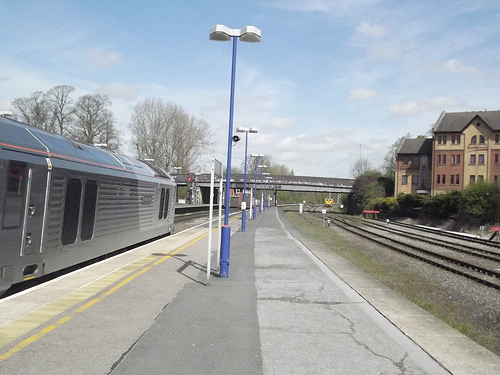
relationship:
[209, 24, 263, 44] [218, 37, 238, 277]
street light mounted on pole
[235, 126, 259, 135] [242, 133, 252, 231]
street light mounted on pole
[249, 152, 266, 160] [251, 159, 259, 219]
street light mounted on pole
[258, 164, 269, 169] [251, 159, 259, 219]
street light mouted on pole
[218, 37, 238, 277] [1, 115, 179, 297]
pole near train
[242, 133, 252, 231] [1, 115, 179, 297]
pole near train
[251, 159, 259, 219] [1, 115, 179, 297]
pole near train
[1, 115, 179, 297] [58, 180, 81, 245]
train has window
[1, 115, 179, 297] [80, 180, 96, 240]
train has window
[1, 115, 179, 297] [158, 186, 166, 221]
train has window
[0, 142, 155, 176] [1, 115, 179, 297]
stripe on top of train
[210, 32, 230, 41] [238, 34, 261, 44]
light next to light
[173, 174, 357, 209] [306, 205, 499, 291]
bridge over tracks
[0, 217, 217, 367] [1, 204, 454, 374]
line painted on platform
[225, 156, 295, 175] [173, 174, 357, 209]
trees behind bridge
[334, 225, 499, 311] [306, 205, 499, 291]
gravel next to tracks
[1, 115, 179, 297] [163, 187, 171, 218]
train has window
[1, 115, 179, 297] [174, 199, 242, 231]
train on top of tracks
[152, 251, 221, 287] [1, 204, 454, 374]
shadow on top of platform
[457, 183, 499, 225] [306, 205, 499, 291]
bush growing near tracks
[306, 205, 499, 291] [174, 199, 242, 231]
tracks parallel to tracks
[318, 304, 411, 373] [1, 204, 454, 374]
crack on surface of platform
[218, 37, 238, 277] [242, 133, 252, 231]
pole in front of pole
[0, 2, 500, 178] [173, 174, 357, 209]
sky above bridge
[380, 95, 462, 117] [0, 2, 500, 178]
cloud floating in sky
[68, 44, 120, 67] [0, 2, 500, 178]
cloud floating in sky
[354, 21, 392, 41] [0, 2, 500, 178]
cloud floating in sky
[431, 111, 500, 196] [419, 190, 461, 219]
building behind bush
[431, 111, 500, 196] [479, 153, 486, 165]
building has window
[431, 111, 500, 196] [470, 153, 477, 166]
building has window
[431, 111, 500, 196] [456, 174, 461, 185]
building has window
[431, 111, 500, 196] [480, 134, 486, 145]
building has window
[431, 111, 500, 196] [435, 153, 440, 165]
building has window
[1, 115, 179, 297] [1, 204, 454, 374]
train next to platform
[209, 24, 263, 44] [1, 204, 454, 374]
street light above platform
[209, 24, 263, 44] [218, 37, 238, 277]
street light attached to pole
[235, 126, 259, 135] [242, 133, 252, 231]
street light attached to pole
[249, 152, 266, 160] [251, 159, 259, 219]
street light attached to pole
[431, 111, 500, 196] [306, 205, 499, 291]
building near tracks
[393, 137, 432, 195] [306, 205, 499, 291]
building near tracks